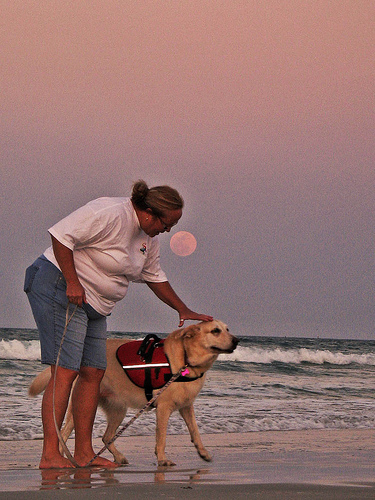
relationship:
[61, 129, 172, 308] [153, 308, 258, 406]
woman with dog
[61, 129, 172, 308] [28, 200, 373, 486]
woman on beach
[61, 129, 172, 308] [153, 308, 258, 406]
woman has dog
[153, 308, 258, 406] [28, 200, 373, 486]
dog on beach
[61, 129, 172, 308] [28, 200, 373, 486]
woman in beach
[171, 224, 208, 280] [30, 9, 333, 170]
moon in sky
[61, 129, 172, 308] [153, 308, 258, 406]
woman petting dog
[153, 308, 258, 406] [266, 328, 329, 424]
dog in water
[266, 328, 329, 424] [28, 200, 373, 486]
water on beach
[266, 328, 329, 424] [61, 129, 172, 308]
water near woman